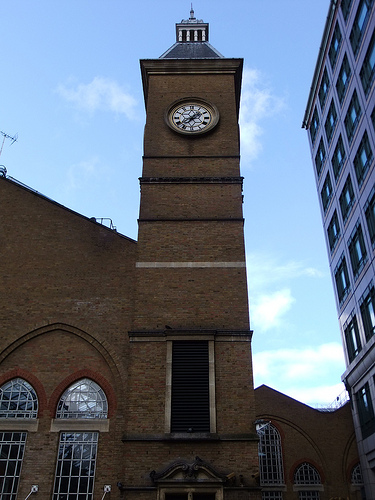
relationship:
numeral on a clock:
[202, 114, 211, 123] [160, 92, 225, 138]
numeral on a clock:
[181, 120, 187, 131] [163, 95, 216, 140]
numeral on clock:
[188, 102, 194, 111] [160, 98, 222, 133]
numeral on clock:
[186, 102, 197, 113] [163, 92, 220, 135]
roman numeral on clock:
[189, 119, 210, 132] [168, 96, 213, 133]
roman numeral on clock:
[186, 123, 194, 129] [163, 89, 223, 143]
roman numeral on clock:
[173, 116, 179, 119] [164, 95, 221, 133]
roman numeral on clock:
[181, 107, 186, 111] [164, 95, 221, 133]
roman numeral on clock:
[201, 109, 207, 114] [164, 95, 221, 133]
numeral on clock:
[203, 115, 209, 120] [164, 95, 221, 133]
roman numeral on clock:
[203, 120, 206, 124] [164, 95, 221, 133]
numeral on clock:
[174, 119, 182, 124] [164, 91, 224, 140]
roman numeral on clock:
[170, 116, 181, 119] [164, 95, 221, 133]